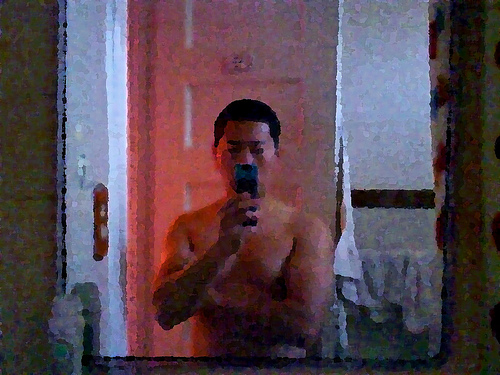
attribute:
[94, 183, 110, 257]
box — red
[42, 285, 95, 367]
bottle — plastic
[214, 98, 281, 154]
hair — black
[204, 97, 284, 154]
black hair — person's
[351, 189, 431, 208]
trim — wood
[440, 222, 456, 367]
rim — blue